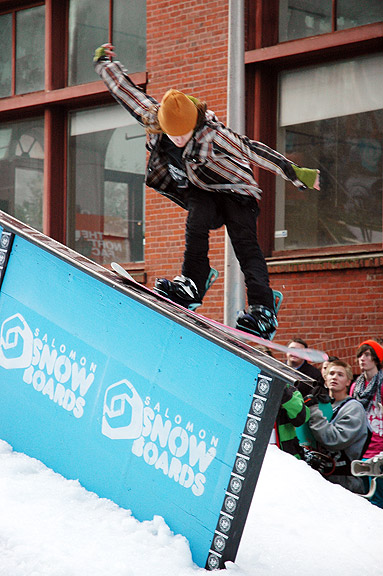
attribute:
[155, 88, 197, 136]
hat — orange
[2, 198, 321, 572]
ramp — snowboard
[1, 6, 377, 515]
building — brick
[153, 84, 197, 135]
hat — orange